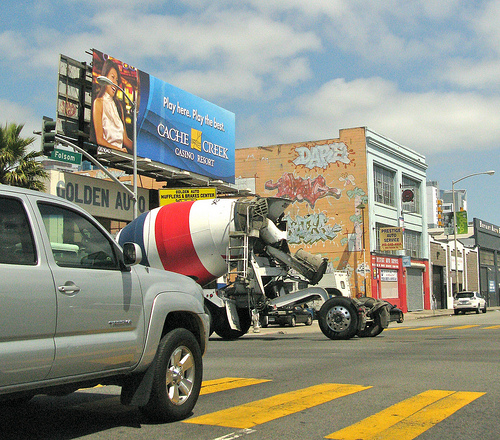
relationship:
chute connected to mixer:
[262, 240, 326, 284] [113, 202, 291, 277]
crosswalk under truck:
[180, 364, 497, 439] [1, 182, 208, 419]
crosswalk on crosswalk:
[180, 364, 497, 439] [180, 364, 497, 439]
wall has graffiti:
[234, 147, 372, 300] [272, 148, 357, 243]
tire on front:
[158, 329, 202, 416] [138, 268, 207, 353]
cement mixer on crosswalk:
[113, 193, 402, 339] [180, 364, 497, 439]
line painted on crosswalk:
[212, 425, 250, 439] [180, 364, 497, 439]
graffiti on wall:
[272, 148, 357, 243] [234, 147, 372, 300]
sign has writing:
[47, 166, 149, 222] [57, 181, 141, 209]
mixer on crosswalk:
[113, 193, 402, 339] [180, 364, 497, 439]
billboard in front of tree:
[59, 47, 240, 184] [0, 122, 49, 188]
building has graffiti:
[235, 137, 438, 314] [272, 148, 357, 243]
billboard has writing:
[59, 47, 240, 184] [153, 94, 230, 170]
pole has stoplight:
[125, 83, 143, 254] [39, 113, 58, 159]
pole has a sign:
[125, 83, 143, 254] [48, 141, 84, 165]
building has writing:
[235, 137, 438, 314] [272, 148, 357, 243]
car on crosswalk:
[454, 290, 489, 312] [180, 364, 497, 439]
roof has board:
[241, 146, 420, 165] [59, 47, 240, 184]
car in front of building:
[454, 290, 489, 312] [235, 137, 438, 314]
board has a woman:
[59, 47, 240, 184] [94, 61, 128, 151]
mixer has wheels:
[113, 202, 291, 277] [315, 294, 362, 341]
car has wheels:
[1, 182, 208, 419] [158, 329, 202, 416]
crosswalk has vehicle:
[180, 364, 497, 439] [1, 182, 208, 419]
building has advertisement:
[36, 165, 152, 225] [59, 47, 240, 184]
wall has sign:
[370, 196, 431, 309] [378, 222, 406, 255]